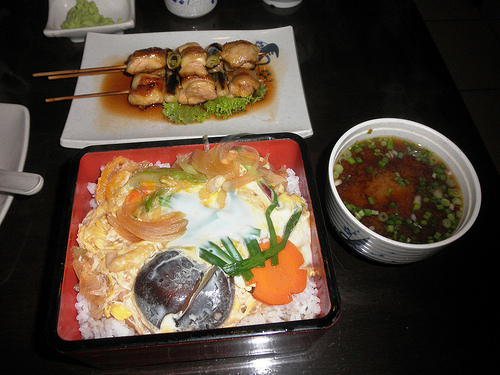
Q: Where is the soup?
A: In the bowl.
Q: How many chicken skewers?
A: 2.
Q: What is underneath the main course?
A: Rice.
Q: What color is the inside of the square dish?
A: Red.